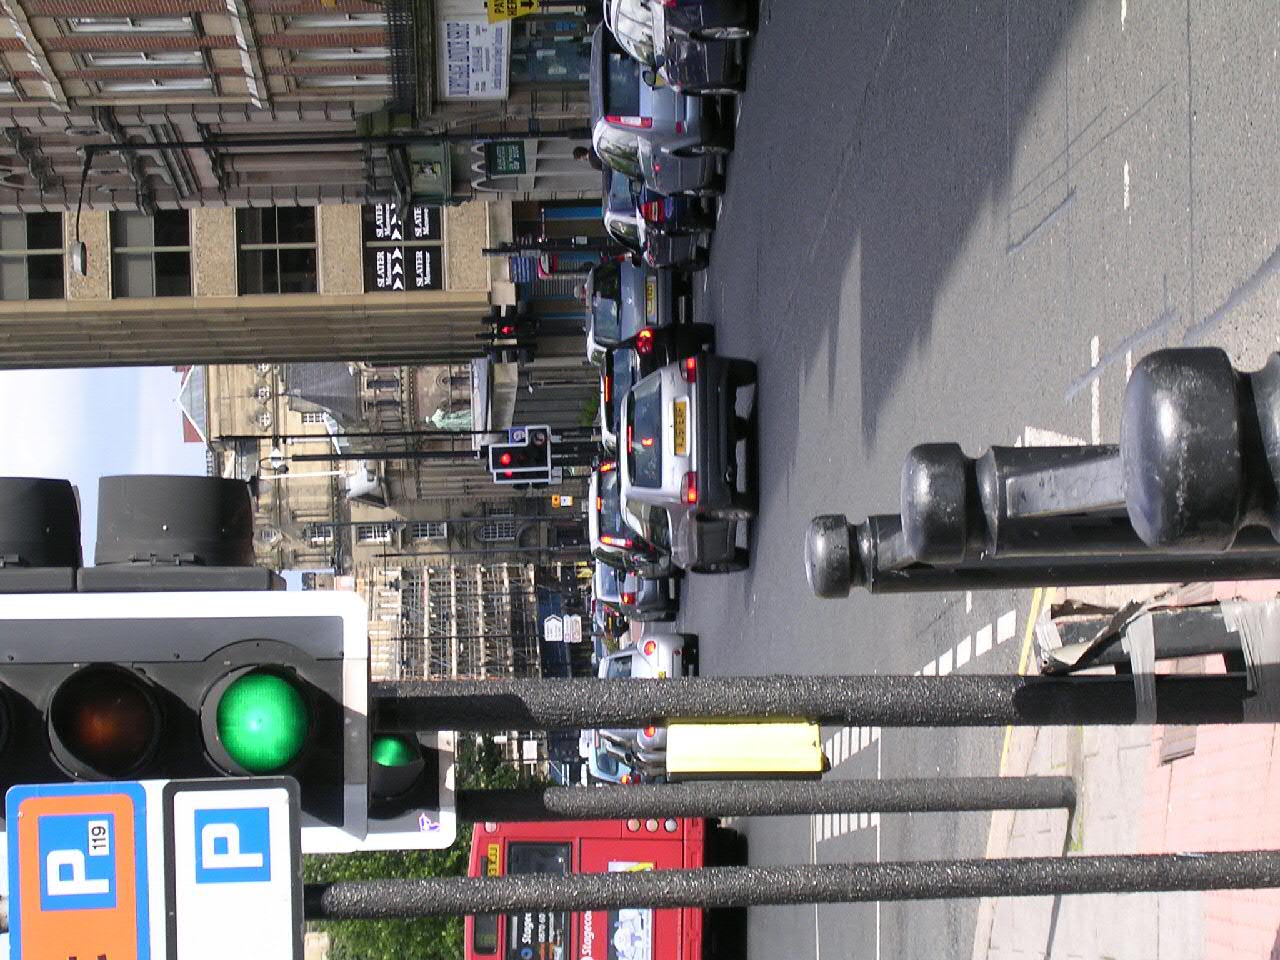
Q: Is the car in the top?
A: Yes, the car is in the top of the image.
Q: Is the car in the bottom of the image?
A: No, the car is in the top of the image.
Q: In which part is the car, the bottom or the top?
A: The car is in the top of the image.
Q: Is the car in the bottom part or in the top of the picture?
A: The car is in the top of the image.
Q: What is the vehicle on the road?
A: The vehicle is a car.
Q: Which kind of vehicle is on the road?
A: The vehicle is a car.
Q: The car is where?
A: The car is on the road.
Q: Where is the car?
A: The car is on the road.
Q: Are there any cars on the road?
A: Yes, there is a car on the road.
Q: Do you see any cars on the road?
A: Yes, there is a car on the road.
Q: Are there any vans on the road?
A: No, there is a car on the road.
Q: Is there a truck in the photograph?
A: No, there are no trucks.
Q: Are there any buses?
A: Yes, there is a bus.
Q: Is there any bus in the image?
A: Yes, there is a bus.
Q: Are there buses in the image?
A: Yes, there is a bus.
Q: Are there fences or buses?
A: Yes, there is a bus.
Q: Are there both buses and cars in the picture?
A: Yes, there are both a bus and a car.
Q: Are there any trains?
A: No, there are no trains.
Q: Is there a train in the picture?
A: No, there are no trains.